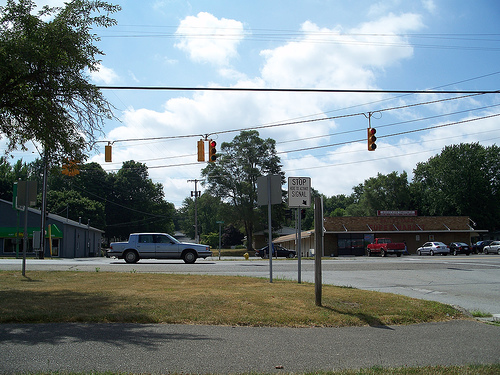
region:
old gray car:
[111, 226, 213, 263]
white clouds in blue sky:
[115, 9, 163, 53]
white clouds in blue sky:
[132, 26, 163, 54]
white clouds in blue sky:
[125, 101, 144, 119]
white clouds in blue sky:
[178, 91, 207, 132]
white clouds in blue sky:
[172, 29, 223, 69]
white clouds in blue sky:
[312, 149, 352, 176]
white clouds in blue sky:
[293, 20, 373, 78]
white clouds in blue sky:
[371, 22, 423, 63]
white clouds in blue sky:
[400, 107, 450, 134]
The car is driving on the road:
[93, 225, 214, 271]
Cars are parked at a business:
[255, 190, 494, 267]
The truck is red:
[357, 233, 412, 266]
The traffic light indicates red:
[179, 119, 234, 167]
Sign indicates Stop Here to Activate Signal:
[280, 160, 335, 281]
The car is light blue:
[103, 224, 220, 274]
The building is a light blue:
[0, 210, 113, 275]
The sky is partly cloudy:
[22, 19, 498, 214]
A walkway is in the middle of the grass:
[10, 291, 495, 371]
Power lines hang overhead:
[66, 80, 481, 176]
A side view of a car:
[97, 214, 225, 270]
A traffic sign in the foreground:
[281, 169, 314, 286]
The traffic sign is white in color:
[283, 173, 313, 286]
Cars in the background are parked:
[363, 233, 498, 260]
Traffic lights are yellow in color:
[181, 122, 384, 168]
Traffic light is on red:
[195, 131, 226, 169]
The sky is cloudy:
[5, 3, 499, 190]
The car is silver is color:
[103, 225, 220, 265]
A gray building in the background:
[0, 186, 108, 262]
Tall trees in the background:
[3, 128, 496, 231]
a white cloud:
[173, 11, 245, 65]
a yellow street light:
[366, 128, 378, 154]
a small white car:
[105, 228, 215, 263]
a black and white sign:
[287, 175, 312, 210]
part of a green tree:
[0, 0, 117, 182]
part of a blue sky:
[420, 52, 479, 83]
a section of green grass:
[1, 266, 463, 331]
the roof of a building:
[321, 216, 475, 235]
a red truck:
[365, 233, 407, 258]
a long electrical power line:
[112, 23, 499, 43]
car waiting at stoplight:
[103, 225, 213, 266]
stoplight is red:
[190, 133, 222, 167]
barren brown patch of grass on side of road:
[3, 260, 472, 331]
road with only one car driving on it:
[3, 228, 499, 323]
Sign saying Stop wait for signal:
[280, 168, 316, 211]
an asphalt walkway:
[6, 309, 496, 370]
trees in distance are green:
[2, 143, 497, 245]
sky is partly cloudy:
[2, 3, 499, 187]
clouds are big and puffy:
[68, 0, 492, 203]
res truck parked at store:
[360, 233, 407, 258]